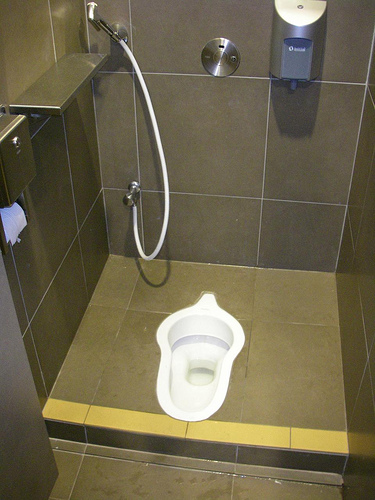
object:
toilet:
[141, 275, 244, 433]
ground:
[105, 261, 289, 499]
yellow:
[242, 416, 284, 455]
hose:
[95, 39, 182, 265]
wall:
[62, 1, 267, 269]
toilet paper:
[3, 132, 43, 247]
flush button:
[197, 34, 247, 90]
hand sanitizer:
[267, 2, 333, 112]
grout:
[237, 468, 284, 486]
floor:
[68, 456, 304, 497]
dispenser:
[0, 112, 66, 249]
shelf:
[26, 45, 117, 129]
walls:
[22, 9, 147, 331]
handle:
[82, 4, 124, 42]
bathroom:
[0, 0, 366, 500]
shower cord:
[114, 173, 146, 215]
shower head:
[79, 0, 120, 22]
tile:
[246, 357, 347, 424]